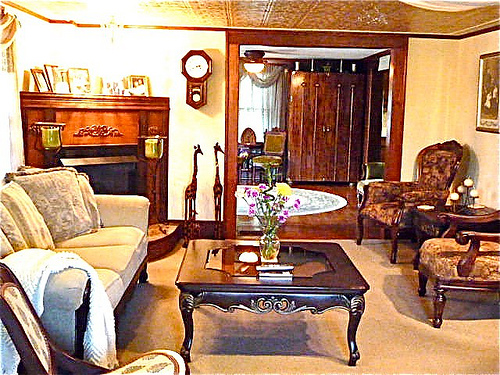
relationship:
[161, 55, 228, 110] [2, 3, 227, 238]
clock on wall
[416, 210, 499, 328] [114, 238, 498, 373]
armchair on carpeting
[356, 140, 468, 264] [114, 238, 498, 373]
arm chair on carpeting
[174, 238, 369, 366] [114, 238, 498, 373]
coffee table on carpeting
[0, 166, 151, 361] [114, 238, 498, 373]
couch on carpeting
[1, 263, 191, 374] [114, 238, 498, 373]
furniture on carpeting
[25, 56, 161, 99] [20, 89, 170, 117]
family photos on mantle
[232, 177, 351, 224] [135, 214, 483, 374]
rug on floor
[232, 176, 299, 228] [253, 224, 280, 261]
flowers in vase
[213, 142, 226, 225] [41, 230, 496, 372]
giraffe statue on floor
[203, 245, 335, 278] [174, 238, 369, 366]
insert in coffee table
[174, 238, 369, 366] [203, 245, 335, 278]
coffee table has insert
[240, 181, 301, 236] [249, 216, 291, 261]
flower arrangement in a vase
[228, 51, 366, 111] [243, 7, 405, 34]
brass tin type ceiling tiles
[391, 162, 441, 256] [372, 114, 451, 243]
framed chair in corner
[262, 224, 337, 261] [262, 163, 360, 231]
vase holding flowers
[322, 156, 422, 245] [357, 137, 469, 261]
two wood framed brown and tan arm chair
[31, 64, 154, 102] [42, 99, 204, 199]
lots of photos in frames on mantle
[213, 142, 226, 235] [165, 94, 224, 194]
statue against wall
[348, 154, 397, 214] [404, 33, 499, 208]
brown patterned arm chair against wall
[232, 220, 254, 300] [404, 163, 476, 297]
candles on side table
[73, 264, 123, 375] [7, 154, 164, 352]
white throw blanket on couch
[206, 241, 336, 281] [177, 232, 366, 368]
glass on top of coffee table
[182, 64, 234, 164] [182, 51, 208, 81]
wooden wall clock with round face